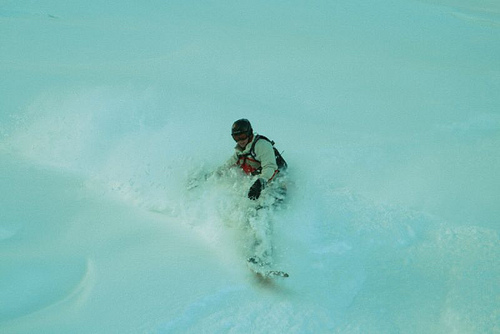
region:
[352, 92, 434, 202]
the snow is white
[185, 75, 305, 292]
the person fell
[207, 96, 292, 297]
the person is covered in snow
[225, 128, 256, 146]
he is wearing goggles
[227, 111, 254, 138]
the person is wearing a helmet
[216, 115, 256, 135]
the helmet is black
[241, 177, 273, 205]
the glove is black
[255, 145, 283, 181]
the jacket is white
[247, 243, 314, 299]
the board is sticking out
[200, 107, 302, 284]
the person is snow boarding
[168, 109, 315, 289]
the person is snowboarding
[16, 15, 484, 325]
the slope is covered in snow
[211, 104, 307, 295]
the person wearing a helmet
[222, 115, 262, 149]
the helmet is black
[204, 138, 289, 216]
the man wearing a jacket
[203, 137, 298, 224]
the jacket is white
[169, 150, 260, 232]
the snow is powdered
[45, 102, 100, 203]
the snow on the mountain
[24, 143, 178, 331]
the snow on the mountain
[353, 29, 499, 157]
the snow on the mountain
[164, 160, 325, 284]
Snow kicked in the air.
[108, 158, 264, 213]
Smow flying up.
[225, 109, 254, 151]
A helmet and googles.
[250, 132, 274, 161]
The shoulder strap for pack.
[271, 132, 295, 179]
A black back pack.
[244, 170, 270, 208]
She is wearing gloves.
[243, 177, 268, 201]
The gloves are black.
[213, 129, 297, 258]
A whiote jacket and pants suit.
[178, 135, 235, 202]
The arm in the snow.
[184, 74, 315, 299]
A person snowboards down the mountain.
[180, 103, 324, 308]
A man is snowboarding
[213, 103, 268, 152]
The helmet is black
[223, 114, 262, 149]
The man is wearing goggles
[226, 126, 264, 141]
Black and red goggles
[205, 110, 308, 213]
White and red jacket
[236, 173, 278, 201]
The man is wearing gloves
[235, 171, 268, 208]
The gloves are black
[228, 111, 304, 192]
The man is wearing a backpack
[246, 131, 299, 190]
The backpack is black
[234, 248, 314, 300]
The snowboard is black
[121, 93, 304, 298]
a man is snowboarding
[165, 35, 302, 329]
a man sitting in the snow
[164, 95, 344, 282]
a man wearing a helmet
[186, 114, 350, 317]
a snowboarder wearing a helmet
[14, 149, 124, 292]
white snow on the ground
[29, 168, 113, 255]
snow on the ground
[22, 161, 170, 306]
ground covered in snow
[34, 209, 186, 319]
snow covered in white snow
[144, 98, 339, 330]
a man surrounded by snow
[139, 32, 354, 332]
a man wearing gloves